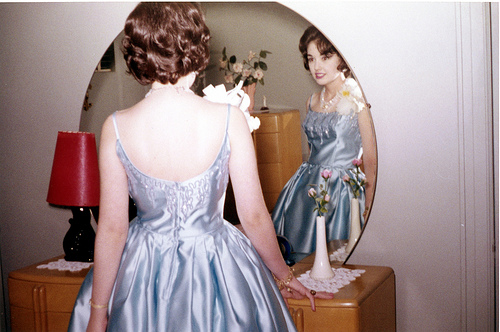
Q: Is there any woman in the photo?
A: Yes, there is a woman.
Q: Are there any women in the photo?
A: Yes, there is a woman.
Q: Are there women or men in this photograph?
A: Yes, there is a woman.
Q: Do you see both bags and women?
A: No, there is a woman but no bags.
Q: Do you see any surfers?
A: No, there are no surfers.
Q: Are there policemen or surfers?
A: No, there are no surfers or policemen.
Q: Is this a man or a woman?
A: This is a woman.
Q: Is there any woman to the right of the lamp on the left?
A: Yes, there is a woman to the right of the lamp.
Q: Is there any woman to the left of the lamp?
A: No, the woman is to the right of the lamp.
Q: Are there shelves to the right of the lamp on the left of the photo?
A: No, there is a woman to the right of the lamp.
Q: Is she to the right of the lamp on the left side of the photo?
A: Yes, the woman is to the right of the lamp.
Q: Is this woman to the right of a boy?
A: No, the woman is to the right of the lamp.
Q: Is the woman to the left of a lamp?
A: No, the woman is to the right of a lamp.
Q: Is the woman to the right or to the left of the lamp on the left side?
A: The woman is to the right of the lamp.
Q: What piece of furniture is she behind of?
A: The woman is behind the dresser.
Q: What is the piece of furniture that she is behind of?
A: The piece of furniture is a dresser.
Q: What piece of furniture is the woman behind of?
A: The woman is behind the dresser.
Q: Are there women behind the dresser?
A: Yes, there is a woman behind the dresser.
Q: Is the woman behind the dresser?
A: Yes, the woman is behind the dresser.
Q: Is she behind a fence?
A: No, the woman is behind the dresser.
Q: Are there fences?
A: No, there are no fences.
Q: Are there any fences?
A: No, there are no fences.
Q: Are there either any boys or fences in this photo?
A: No, there are no fences or boys.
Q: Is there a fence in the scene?
A: No, there are no fences.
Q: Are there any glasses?
A: No, there are no glasses.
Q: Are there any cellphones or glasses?
A: No, there are no glasses or cellphones.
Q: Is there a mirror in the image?
A: Yes, there is a mirror.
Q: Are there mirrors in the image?
A: Yes, there is a mirror.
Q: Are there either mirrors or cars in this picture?
A: Yes, there is a mirror.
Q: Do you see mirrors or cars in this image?
A: Yes, there is a mirror.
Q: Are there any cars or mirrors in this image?
A: Yes, there is a mirror.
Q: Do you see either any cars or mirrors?
A: Yes, there is a mirror.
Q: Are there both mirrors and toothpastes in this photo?
A: No, there is a mirror but no toothpastes.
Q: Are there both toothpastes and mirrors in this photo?
A: No, there is a mirror but no toothpastes.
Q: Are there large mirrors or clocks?
A: Yes, there is a large mirror.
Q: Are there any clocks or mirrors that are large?
A: Yes, the mirror is large.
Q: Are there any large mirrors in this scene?
A: Yes, there is a large mirror.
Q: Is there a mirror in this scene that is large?
A: Yes, there is a mirror that is large.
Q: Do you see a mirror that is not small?
A: Yes, there is a large mirror.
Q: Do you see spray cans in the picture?
A: No, there are no spray cans.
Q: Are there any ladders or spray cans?
A: No, there are no spray cans or ladders.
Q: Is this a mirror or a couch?
A: This is a mirror.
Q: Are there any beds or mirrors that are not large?
A: No, there is a mirror but it is large.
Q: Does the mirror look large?
A: Yes, the mirror is large.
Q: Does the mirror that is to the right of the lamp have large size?
A: Yes, the mirror is large.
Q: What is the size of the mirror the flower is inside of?
A: The mirror is large.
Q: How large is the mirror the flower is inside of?
A: The mirror is large.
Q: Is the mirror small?
A: No, the mirror is large.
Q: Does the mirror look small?
A: No, the mirror is large.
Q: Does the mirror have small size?
A: No, the mirror is large.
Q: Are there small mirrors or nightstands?
A: No, there is a mirror but it is large.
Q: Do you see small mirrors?
A: No, there is a mirror but it is large.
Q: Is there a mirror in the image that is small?
A: No, there is a mirror but it is large.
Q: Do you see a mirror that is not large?
A: No, there is a mirror but it is large.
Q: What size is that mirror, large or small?
A: The mirror is large.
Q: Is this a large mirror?
A: Yes, this is a large mirror.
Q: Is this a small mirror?
A: No, this is a large mirror.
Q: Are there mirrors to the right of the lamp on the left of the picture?
A: Yes, there is a mirror to the right of the lamp.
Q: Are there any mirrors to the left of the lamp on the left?
A: No, the mirror is to the right of the lamp.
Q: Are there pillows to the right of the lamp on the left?
A: No, there is a mirror to the right of the lamp.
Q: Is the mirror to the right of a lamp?
A: Yes, the mirror is to the right of a lamp.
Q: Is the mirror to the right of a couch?
A: No, the mirror is to the right of a lamp.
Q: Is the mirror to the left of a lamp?
A: No, the mirror is to the right of a lamp.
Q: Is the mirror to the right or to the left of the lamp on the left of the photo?
A: The mirror is to the right of the lamp.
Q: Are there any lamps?
A: Yes, there is a lamp.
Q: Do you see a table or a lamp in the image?
A: Yes, there is a lamp.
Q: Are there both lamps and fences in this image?
A: No, there is a lamp but no fences.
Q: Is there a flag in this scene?
A: No, there are no flags.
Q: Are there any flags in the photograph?
A: No, there are no flags.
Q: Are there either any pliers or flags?
A: No, there are no flags or pliers.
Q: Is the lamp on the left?
A: Yes, the lamp is on the left of the image.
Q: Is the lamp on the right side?
A: No, the lamp is on the left of the image.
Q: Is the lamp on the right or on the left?
A: The lamp is on the left of the image.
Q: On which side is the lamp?
A: The lamp is on the left of the image.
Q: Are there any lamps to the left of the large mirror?
A: Yes, there is a lamp to the left of the mirror.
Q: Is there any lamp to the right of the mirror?
A: No, the lamp is to the left of the mirror.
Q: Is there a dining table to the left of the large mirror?
A: No, there is a lamp to the left of the mirror.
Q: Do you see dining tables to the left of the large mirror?
A: No, there is a lamp to the left of the mirror.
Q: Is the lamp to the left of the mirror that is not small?
A: Yes, the lamp is to the left of the mirror.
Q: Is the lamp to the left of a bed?
A: No, the lamp is to the left of the mirror.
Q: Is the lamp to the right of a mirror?
A: No, the lamp is to the left of a mirror.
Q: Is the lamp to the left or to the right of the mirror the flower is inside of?
A: The lamp is to the left of the mirror.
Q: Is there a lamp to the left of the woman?
A: Yes, there is a lamp to the left of the woman.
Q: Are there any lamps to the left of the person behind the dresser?
A: Yes, there is a lamp to the left of the woman.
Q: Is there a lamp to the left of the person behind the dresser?
A: Yes, there is a lamp to the left of the woman.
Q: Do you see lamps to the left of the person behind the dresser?
A: Yes, there is a lamp to the left of the woman.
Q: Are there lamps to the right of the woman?
A: No, the lamp is to the left of the woman.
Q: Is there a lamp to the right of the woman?
A: No, the lamp is to the left of the woman.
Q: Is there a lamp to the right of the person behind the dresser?
A: No, the lamp is to the left of the woman.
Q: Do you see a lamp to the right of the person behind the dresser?
A: No, the lamp is to the left of the woman.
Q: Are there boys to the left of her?
A: No, there is a lamp to the left of the woman.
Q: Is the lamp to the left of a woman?
A: Yes, the lamp is to the left of a woman.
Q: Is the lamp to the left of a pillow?
A: No, the lamp is to the left of a woman.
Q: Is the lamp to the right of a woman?
A: No, the lamp is to the left of a woman.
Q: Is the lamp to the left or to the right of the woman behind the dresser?
A: The lamp is to the left of the woman.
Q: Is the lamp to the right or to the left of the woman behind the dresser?
A: The lamp is to the left of the woman.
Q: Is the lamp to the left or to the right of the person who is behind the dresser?
A: The lamp is to the left of the woman.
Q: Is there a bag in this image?
A: No, there are no bags.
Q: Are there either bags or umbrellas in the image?
A: No, there are no bags or umbrellas.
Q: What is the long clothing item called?
A: The clothing item is a dress.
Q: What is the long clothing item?
A: The clothing item is a dress.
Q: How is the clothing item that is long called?
A: The clothing item is a dress.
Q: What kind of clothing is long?
A: The clothing is a dress.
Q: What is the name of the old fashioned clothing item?
A: The clothing item is a dress.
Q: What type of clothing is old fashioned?
A: The clothing is a dress.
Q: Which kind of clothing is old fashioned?
A: The clothing is a dress.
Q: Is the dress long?
A: Yes, the dress is long.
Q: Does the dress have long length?
A: Yes, the dress is long.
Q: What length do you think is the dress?
A: The dress is long.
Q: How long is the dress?
A: The dress is long.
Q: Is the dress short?
A: No, the dress is long.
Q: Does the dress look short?
A: No, the dress is long.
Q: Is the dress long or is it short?
A: The dress is long.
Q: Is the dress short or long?
A: The dress is long.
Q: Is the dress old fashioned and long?
A: Yes, the dress is old fashioned and long.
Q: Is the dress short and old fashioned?
A: No, the dress is old fashioned but long.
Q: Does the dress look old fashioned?
A: Yes, the dress is old fashioned.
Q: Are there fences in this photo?
A: No, there are no fences.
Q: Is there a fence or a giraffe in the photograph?
A: No, there are no fences or giraffes.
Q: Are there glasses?
A: No, there are no glasses.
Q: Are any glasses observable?
A: No, there are no glasses.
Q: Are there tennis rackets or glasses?
A: No, there are no glasses or tennis rackets.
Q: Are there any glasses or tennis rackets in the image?
A: No, there are no glasses or tennis rackets.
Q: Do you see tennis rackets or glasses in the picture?
A: No, there are no glasses or tennis rackets.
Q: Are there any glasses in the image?
A: No, there are no glasses.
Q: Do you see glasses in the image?
A: No, there are no glasses.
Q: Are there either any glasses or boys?
A: No, there are no glasses or boys.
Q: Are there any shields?
A: No, there are no shields.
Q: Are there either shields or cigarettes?
A: No, there are no shields or cigarettes.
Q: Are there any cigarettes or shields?
A: No, there are no shields or cigarettes.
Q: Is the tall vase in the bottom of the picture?
A: Yes, the vase is in the bottom of the image.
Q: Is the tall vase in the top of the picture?
A: No, the vase is in the bottom of the image.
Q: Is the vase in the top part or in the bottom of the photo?
A: The vase is in the bottom of the image.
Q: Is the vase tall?
A: Yes, the vase is tall.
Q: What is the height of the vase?
A: The vase is tall.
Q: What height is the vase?
A: The vase is tall.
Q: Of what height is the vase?
A: The vase is tall.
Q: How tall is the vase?
A: The vase is tall.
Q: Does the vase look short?
A: No, the vase is tall.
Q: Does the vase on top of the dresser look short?
A: No, the vase is tall.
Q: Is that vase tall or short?
A: The vase is tall.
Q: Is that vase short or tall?
A: The vase is tall.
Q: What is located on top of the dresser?
A: The vase is on top of the dresser.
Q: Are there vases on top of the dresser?
A: Yes, there is a vase on top of the dresser.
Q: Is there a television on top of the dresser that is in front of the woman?
A: No, there is a vase on top of the dresser.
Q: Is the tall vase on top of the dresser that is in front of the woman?
A: Yes, the vase is on top of the dresser.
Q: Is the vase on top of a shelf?
A: No, the vase is on top of the dresser.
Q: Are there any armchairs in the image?
A: No, there are no armchairs.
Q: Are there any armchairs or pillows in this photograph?
A: No, there are no armchairs or pillows.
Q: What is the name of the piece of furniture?
A: The piece of furniture is a dresser.